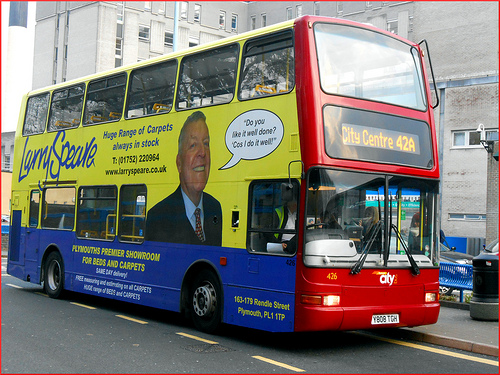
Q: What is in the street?
A: Bus.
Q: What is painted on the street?
A: Lines.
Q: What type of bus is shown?
A: Double decker.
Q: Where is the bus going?
A: City Centre.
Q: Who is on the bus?
A: A man.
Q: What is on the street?
A: A double decker bus.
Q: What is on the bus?
A: Advertisements.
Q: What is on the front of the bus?
A: RED PAINT.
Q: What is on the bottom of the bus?
A: Blue paint.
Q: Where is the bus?
A: Parked on the street.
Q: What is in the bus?
A: Seats.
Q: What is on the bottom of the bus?
A: Blue paint.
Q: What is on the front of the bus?
A: Red Paint.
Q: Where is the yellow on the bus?
A: On the side.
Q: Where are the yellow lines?
A: On the street.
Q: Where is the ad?
A: On the bus.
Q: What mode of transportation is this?
A: A bus.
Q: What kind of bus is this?
A: A double decker.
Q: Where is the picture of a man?
A: On the side of the bus.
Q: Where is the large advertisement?
A: On the side of the bus.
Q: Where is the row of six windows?
A: On the upper level.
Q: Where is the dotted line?
A: On the ground.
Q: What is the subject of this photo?
A: A bus.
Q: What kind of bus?
A: Double-decker.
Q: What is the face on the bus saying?
A: "Do you like it well cone? 'Cos I do it well!".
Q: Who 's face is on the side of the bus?
A: Larry Speare.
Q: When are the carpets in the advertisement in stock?
A: Always.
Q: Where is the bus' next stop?
A: City Center.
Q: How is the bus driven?
A: By a bus driver.